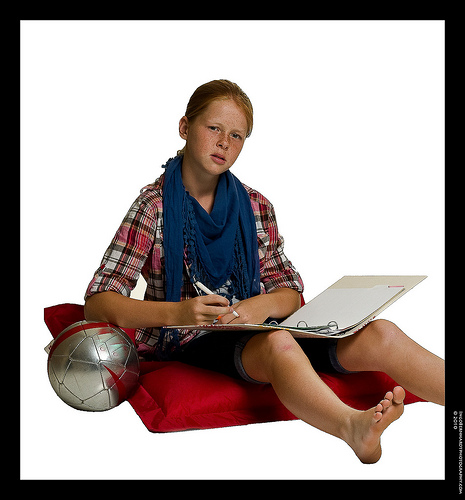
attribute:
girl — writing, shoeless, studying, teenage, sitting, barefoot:
[84, 79, 444, 462]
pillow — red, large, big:
[43, 302, 428, 431]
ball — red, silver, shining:
[45, 321, 140, 411]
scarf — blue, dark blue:
[150, 156, 258, 368]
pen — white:
[193, 280, 238, 320]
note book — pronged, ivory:
[162, 275, 426, 338]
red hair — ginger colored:
[185, 80, 253, 137]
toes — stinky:
[371, 386, 404, 420]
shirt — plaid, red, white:
[84, 174, 304, 359]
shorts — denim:
[165, 330, 360, 383]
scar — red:
[282, 345, 293, 350]